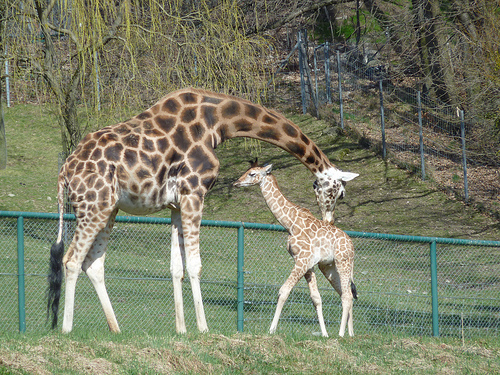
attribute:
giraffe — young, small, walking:
[244, 155, 354, 348]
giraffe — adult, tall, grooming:
[0, 93, 327, 318]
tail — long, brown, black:
[18, 150, 83, 333]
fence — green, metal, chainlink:
[351, 201, 498, 370]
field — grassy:
[359, 335, 471, 374]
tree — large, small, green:
[9, 10, 313, 183]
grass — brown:
[303, 338, 488, 374]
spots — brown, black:
[279, 192, 337, 259]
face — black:
[316, 156, 349, 229]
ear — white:
[345, 169, 362, 190]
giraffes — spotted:
[65, 80, 363, 354]